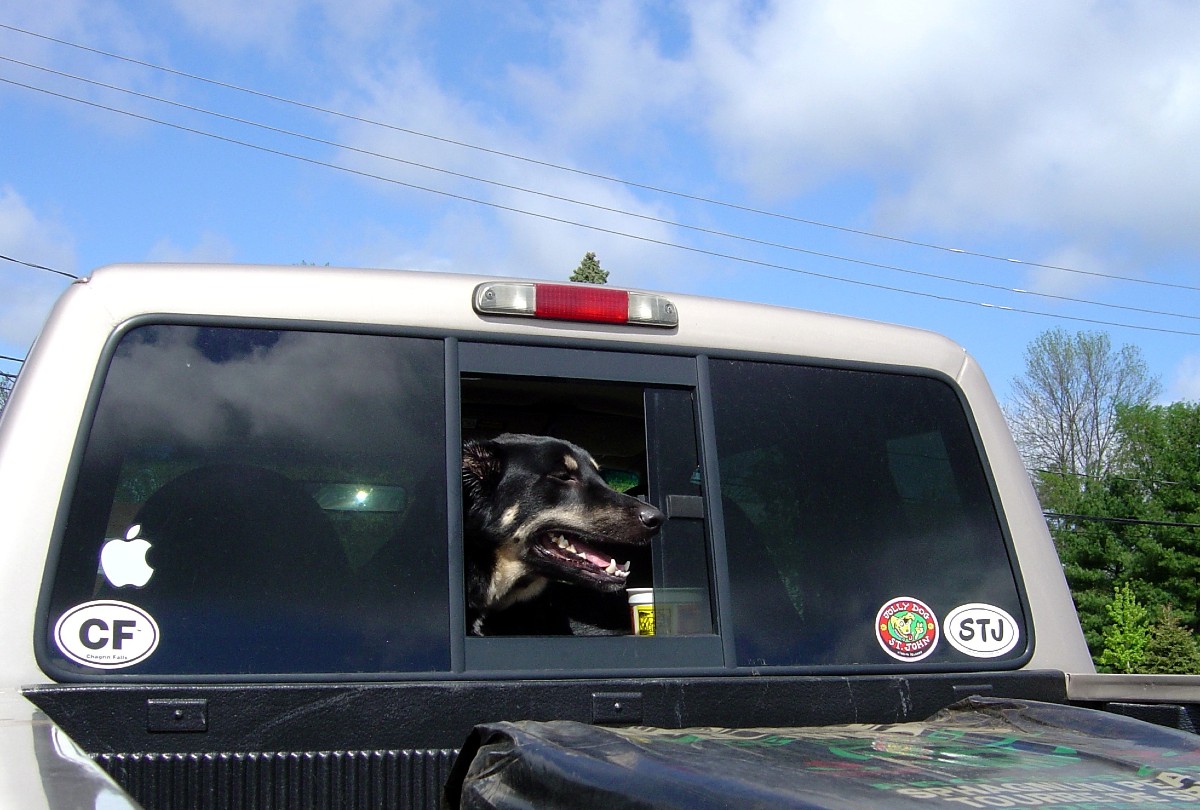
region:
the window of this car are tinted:
[250, 477, 385, 631]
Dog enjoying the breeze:
[390, 248, 739, 690]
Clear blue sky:
[50, 24, 891, 231]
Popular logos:
[34, 504, 214, 701]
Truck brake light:
[437, 246, 701, 350]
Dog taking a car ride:
[428, 354, 709, 671]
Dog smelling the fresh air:
[421, 306, 709, 691]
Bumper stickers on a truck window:
[865, 567, 1038, 688]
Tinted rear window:
[29, 293, 1062, 716]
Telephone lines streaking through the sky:
[48, 29, 1191, 317]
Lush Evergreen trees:
[1058, 342, 1198, 690]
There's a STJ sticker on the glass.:
[942, 596, 1032, 659]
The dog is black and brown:
[443, 411, 700, 645]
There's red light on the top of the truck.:
[484, 276, 713, 329]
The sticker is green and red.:
[854, 574, 948, 673]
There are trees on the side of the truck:
[1020, 336, 1198, 689]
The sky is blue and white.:
[191, 60, 905, 174]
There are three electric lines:
[189, 54, 1089, 304]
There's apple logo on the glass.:
[81, 516, 202, 589]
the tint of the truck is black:
[626, 584, 1018, 657]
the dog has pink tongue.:
[463, 435, 660, 640]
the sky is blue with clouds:
[18, 13, 1195, 259]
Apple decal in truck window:
[98, 521, 156, 591]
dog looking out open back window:
[460, 366, 669, 643]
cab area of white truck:
[5, 262, 1105, 682]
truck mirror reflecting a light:
[299, 478, 412, 517]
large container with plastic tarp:
[448, 694, 1198, 805]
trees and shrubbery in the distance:
[1009, 322, 1195, 676]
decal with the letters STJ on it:
[942, 598, 1020, 658]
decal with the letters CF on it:
[49, 593, 162, 668]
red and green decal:
[872, 594, 938, 660]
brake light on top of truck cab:
[470, 277, 680, 331]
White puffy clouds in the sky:
[713, 28, 1124, 281]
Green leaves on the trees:
[1067, 428, 1197, 674]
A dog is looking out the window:
[448, 386, 683, 655]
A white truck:
[45, 172, 1148, 732]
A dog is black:
[393, 386, 681, 655]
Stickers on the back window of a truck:
[857, 569, 1030, 708]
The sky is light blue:
[112, 153, 221, 221]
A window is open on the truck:
[386, 277, 797, 725]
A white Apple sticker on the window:
[55, 457, 173, 614]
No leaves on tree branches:
[1005, 309, 1149, 432]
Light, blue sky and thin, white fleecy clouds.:
[120, 41, 1119, 291]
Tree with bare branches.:
[1021, 315, 1165, 522]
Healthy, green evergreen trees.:
[1076, 442, 1197, 675]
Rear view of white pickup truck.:
[53, 214, 1181, 795]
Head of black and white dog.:
[438, 426, 690, 667]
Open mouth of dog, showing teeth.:
[529, 528, 674, 641]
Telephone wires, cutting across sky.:
[96, 75, 1059, 220]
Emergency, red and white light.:
[456, 288, 750, 358]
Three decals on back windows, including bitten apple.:
[22, 536, 1112, 733]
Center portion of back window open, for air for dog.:
[420, 356, 814, 724]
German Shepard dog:
[335, 426, 659, 648]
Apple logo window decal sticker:
[98, 517, 156, 589]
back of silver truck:
[2, 265, 1198, 803]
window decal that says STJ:
[940, 600, 1020, 653]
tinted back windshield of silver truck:
[43, 315, 1035, 663]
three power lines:
[2, 18, 1196, 342]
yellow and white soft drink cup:
[624, 579, 708, 633]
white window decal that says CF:
[52, 594, 163, 666]